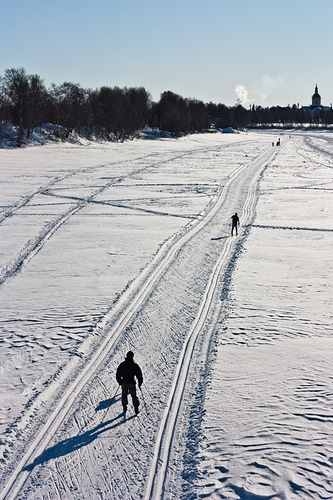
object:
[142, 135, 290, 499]
tracks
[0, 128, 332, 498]
snow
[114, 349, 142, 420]
man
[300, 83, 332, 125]
building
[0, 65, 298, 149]
trees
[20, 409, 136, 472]
shadow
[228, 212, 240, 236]
man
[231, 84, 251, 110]
cloud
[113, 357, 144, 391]
jacket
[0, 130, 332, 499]
field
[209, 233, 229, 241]
shadow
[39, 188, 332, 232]
ridges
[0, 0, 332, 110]
sky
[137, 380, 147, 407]
pole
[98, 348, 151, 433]
skiing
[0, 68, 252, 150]
cluster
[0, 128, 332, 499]
roadway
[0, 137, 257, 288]
ripples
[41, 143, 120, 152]
line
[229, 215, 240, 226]
clothing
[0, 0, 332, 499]
winter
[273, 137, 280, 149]
people